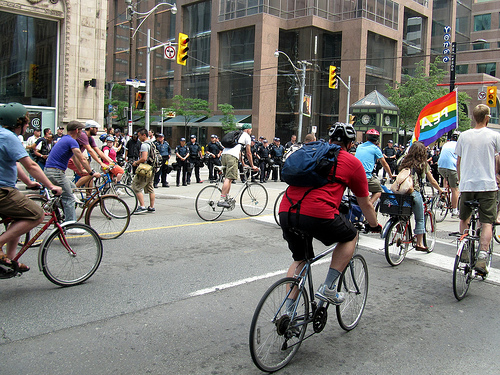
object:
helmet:
[327, 122, 357, 141]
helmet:
[366, 129, 379, 137]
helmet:
[106, 136, 115, 142]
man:
[43, 120, 101, 235]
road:
[0, 133, 500, 375]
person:
[353, 129, 397, 205]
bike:
[431, 173, 461, 223]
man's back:
[289, 148, 342, 202]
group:
[7, 94, 499, 322]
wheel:
[248, 276, 310, 372]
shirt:
[278, 149, 368, 219]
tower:
[349, 90, 400, 149]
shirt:
[354, 141, 384, 180]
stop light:
[329, 65, 337, 89]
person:
[277, 119, 383, 333]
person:
[67, 120, 113, 207]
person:
[0, 102, 63, 273]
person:
[392, 142, 444, 252]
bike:
[0, 187, 103, 288]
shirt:
[46, 135, 80, 171]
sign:
[163, 45, 176, 61]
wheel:
[335, 254, 370, 331]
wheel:
[240, 183, 268, 216]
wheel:
[41, 223, 104, 286]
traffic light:
[176, 33, 189, 66]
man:
[453, 104, 500, 274]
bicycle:
[448, 200, 493, 301]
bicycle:
[196, 165, 268, 221]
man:
[218, 123, 258, 206]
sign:
[442, 26, 451, 64]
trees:
[102, 73, 237, 144]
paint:
[186, 255, 338, 300]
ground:
[0, 152, 500, 375]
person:
[1, 97, 58, 275]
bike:
[249, 220, 369, 371]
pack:
[281, 139, 341, 187]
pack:
[222, 129, 243, 148]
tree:
[389, 70, 471, 169]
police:
[132, 131, 285, 187]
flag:
[409, 86, 458, 147]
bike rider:
[437, 131, 460, 219]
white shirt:
[452, 129, 498, 194]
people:
[0, 103, 62, 274]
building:
[0, 0, 500, 190]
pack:
[391, 167, 413, 195]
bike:
[380, 191, 437, 266]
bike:
[8, 173, 131, 248]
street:
[0, 174, 500, 367]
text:
[421, 106, 448, 129]